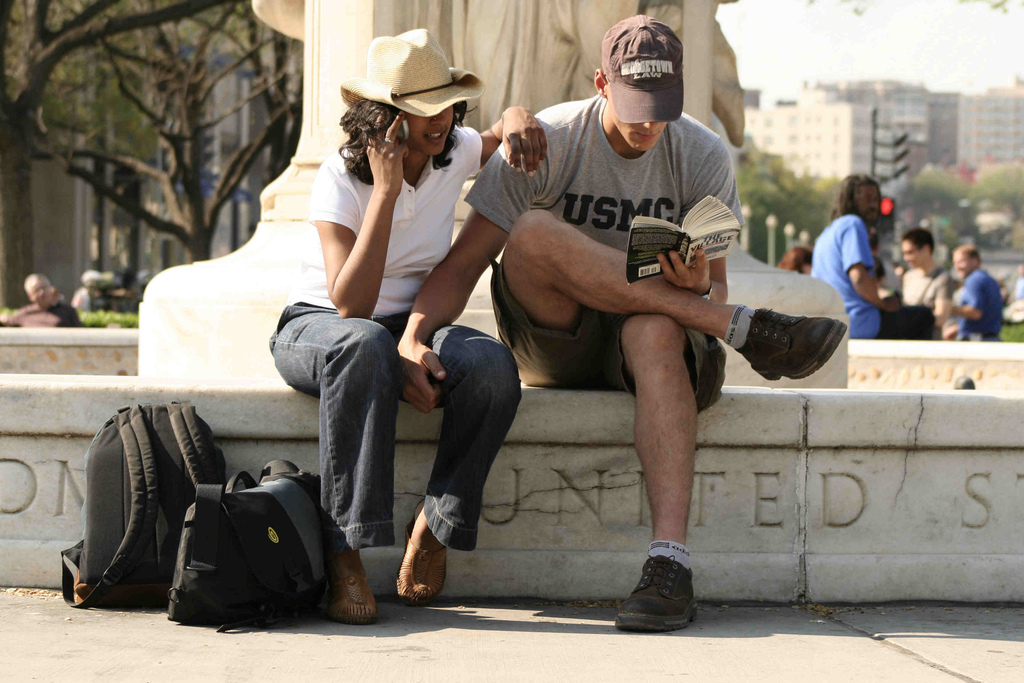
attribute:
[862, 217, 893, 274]
person — standing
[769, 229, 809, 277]
person — standing up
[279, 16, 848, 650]
people — sitting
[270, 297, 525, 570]
jeans — dark blue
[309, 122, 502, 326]
shirt — white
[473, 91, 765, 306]
shirt — gray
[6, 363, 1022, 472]
ledge — stone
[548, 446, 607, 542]
letter — in a wall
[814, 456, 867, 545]
letter — in a wall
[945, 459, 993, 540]
letter — in a wall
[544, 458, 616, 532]
letter — in a wall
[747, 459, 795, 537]
letter — in a wall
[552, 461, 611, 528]
letter — in a wall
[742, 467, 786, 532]
letter — in a wall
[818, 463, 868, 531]
letter — in a wall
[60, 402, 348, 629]
backpacks — black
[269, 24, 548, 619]
woman — blue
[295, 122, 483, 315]
shirt — white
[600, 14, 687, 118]
baseball cap — brown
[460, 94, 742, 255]
tshirt — grey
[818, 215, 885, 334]
tshirt — blue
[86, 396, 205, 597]
straps — black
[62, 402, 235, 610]
backpack — black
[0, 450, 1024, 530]
words — carved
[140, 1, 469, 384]
statue — white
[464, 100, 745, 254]
shirt — grey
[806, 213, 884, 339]
shirt — blue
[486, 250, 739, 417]
shorts — rosado